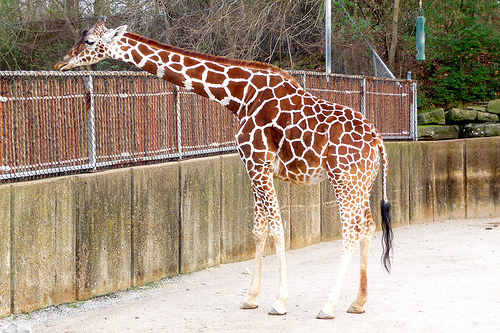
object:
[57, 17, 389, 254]
spot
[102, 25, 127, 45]
ear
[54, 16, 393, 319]
animal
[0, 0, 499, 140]
trees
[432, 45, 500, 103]
leaves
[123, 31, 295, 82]
hair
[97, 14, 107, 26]
ossicones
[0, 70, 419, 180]
fence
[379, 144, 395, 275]
tail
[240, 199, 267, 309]
leg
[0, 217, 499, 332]
ground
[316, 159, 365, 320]
leg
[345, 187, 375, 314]
leg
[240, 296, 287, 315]
hoof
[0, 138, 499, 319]
wall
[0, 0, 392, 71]
branches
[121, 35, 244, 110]
giraffe's neck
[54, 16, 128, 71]
giraffe's head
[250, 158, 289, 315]
leg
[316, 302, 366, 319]
hoof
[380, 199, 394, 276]
tail hair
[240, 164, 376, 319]
giraffe's legs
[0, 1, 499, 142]
background